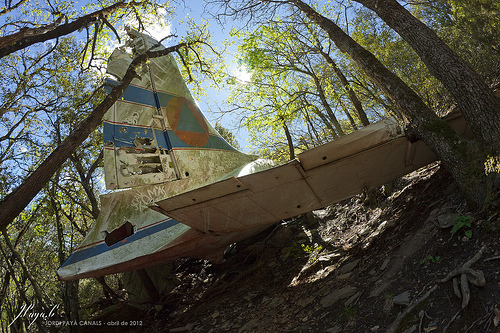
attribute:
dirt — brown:
[91, 262, 498, 324]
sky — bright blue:
[24, 50, 70, 79]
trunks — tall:
[296, 5, 498, 216]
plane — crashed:
[54, 28, 475, 283]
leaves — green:
[447, 0, 499, 53]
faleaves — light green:
[221, 34, 307, 116]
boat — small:
[67, 37, 452, 247]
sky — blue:
[2, 4, 494, 200]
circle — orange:
[164, 95, 212, 147]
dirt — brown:
[281, 253, 386, 293]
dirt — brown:
[171, 267, 253, 324]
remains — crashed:
[47, 23, 497, 288]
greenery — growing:
[403, 218, 460, 291]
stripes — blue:
[90, 69, 237, 169]